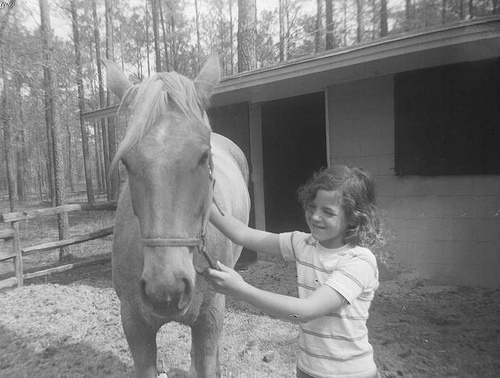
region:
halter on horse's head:
[137, 210, 229, 277]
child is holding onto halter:
[196, 244, 248, 301]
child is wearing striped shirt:
[275, 230, 382, 376]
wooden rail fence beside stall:
[0, 210, 132, 279]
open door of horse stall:
[253, 86, 345, 253]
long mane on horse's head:
[102, 68, 214, 180]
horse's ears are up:
[96, 43, 231, 110]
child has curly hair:
[293, 163, 390, 259]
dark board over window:
[390, 64, 497, 182]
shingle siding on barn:
[390, 179, 497, 268]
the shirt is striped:
[273, 222, 383, 377]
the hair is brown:
[306, 165, 389, 244]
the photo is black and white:
[0, 0, 496, 376]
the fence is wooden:
[12, 194, 117, 279]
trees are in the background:
[0, 0, 437, 35]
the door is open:
[255, 110, 322, 235]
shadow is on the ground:
[8, 330, 113, 377]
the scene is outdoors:
[1, 4, 497, 376]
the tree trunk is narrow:
[43, 10, 67, 257]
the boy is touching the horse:
[206, 182, 384, 376]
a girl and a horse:
[76, 72, 431, 377]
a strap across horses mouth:
[127, 214, 230, 269]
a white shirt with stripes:
[238, 211, 403, 375]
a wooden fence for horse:
[5, 182, 144, 294]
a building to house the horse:
[205, 37, 498, 299]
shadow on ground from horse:
[1, 315, 127, 377]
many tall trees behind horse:
[5, 2, 497, 234]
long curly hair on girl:
[287, 140, 398, 281]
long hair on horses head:
[86, 56, 216, 153]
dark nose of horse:
[115, 271, 211, 324]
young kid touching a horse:
[74, 49, 409, 376]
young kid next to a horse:
[64, 45, 409, 376]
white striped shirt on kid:
[297, 233, 381, 357]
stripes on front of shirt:
[291, 258, 345, 285]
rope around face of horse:
[122, 221, 209, 265]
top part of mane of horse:
[135, 75, 200, 116]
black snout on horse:
[135, 272, 197, 320]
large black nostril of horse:
[171, 273, 191, 305]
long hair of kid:
[348, 196, 395, 263]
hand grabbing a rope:
[200, 239, 234, 299]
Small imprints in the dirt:
[8, 351, 38, 375]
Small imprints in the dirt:
[7, 290, 29, 317]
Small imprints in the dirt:
[6, 304, 40, 341]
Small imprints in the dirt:
[19, 336, 63, 371]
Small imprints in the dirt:
[55, 270, 86, 315]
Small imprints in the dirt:
[76, 318, 100, 343]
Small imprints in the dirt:
[418, 283, 467, 336]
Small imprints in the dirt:
[379, 311, 414, 349]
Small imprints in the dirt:
[430, 326, 499, 370]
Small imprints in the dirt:
[233, 315, 293, 358]